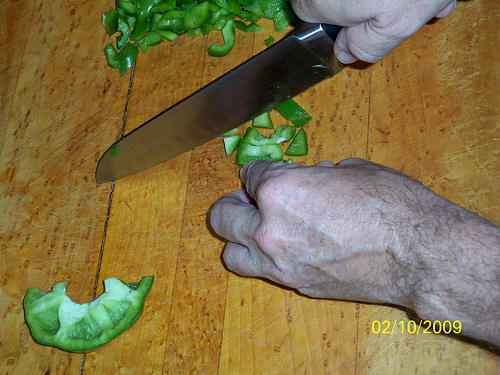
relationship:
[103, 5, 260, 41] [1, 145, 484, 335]
cuts on table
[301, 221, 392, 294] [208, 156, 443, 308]
veins on left hand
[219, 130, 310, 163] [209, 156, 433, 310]
vegetables on hand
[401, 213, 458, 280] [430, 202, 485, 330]
hair on arm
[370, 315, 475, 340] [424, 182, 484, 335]
stamp by arm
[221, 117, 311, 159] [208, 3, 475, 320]
pepper by hands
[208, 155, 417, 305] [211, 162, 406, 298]
pepper by hand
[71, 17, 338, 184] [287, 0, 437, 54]
knife by hand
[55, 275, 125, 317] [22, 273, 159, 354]
membrane of vegetable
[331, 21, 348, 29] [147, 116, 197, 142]
handle of a knife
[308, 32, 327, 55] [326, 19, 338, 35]
trim between handle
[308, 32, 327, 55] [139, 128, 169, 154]
trim between blade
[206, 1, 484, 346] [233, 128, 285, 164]
man preparing pepper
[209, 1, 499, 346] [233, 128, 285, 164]
man cutting pepper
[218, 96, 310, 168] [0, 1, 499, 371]
vegetable being prepared on board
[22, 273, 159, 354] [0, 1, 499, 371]
vegetable being prepared on board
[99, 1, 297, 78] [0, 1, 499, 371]
vegetable being prepared on board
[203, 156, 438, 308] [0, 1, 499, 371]
left hand resting on board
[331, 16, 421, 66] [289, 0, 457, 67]
thumb attached to hand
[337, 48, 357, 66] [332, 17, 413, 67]
nail growing on thumb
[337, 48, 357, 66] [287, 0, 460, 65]
nail growing on hand